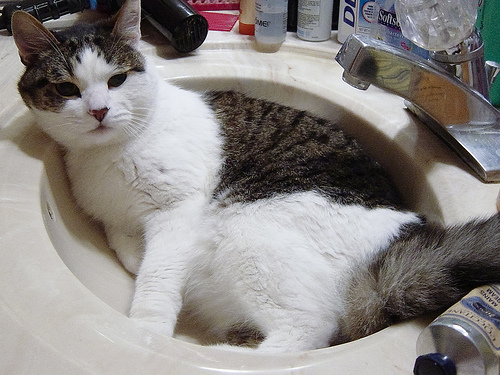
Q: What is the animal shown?
A: Cat.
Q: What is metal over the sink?
A: Faucet.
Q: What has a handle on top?
A: Faucet.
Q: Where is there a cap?
A: Top of tube.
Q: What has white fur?
A: Cat.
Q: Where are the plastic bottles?
A: Back of sink behind cat.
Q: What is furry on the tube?
A: Cat tail.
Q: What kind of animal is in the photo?
A: A cat.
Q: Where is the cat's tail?
A: On the counter.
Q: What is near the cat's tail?
A: A tube of cream.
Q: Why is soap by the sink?
A: For washing hands.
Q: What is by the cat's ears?
A: A hair dryer.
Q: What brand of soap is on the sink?
A: Softsoap.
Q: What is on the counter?
A: Beauty products.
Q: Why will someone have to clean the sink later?
A: Cat hair.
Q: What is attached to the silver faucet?
A: A clear knob.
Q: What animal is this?
A: Cat.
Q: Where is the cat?
A: Sink.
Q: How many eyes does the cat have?
A: Two.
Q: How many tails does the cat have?
A: One.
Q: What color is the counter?
A: Beige.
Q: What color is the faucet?
A: Silver.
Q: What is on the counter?
A: Bottles.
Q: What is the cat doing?
A: Laying down.